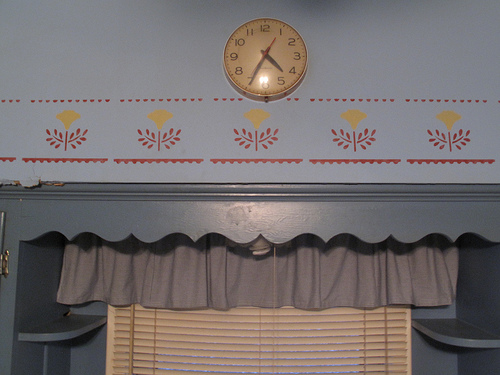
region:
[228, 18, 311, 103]
white clock on wall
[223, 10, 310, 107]
small white clock on wall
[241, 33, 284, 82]
red seconds hand on clock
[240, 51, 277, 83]
long black minute hand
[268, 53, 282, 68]
short black hour hand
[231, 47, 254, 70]
numbers on side of clock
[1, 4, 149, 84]
blue wall color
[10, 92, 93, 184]
red and yellow flowers painted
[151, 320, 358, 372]
white blinds hanging down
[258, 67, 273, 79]
small glare on clock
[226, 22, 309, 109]
small clock on the wall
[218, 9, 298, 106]
white clock on the wall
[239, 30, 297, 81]
white face of clock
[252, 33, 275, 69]
red seconds hand on clock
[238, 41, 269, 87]
black long hand of clock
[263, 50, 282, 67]
black short hand of clock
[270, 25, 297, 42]
numbers on side of lcock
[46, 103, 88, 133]
yellow flower on wall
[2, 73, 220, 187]
wall paper on the wall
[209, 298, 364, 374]
white blinds hanging down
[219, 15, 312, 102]
round clock on wall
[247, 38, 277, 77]
second hand on clock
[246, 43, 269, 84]
minute hand on clock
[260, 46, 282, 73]
hour hand on clock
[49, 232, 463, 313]
blue valance above window blinds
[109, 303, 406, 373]
window blinds hanging on a window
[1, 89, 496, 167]
border on wall below clock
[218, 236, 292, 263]
socket to stick a light bulb in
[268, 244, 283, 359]
string to turn light bulb on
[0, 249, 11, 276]
hinge on cabinet door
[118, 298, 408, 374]
white blinds over the window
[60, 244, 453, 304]
grey curtains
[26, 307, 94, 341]
a blue shelf next to the window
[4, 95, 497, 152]
flowers painted on the wall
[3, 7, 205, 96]
a blue wall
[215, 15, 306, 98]
a clock on the wall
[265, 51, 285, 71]
the hour hand on the clock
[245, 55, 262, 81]
the minute hand on the clock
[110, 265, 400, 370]
a window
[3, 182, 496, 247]
the top of a blue cabinet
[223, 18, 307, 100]
clock under curved glass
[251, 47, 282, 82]
two black clock hands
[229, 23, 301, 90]
black numbers on clock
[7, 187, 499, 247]
blue wood valance over window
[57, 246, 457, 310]
blue valance over blinds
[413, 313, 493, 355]
empty blue shelf next to window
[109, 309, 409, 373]
closed blinds on window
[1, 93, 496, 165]
stencil painted on wall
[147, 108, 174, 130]
yellow flower on wall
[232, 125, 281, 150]
red painted designs on wall